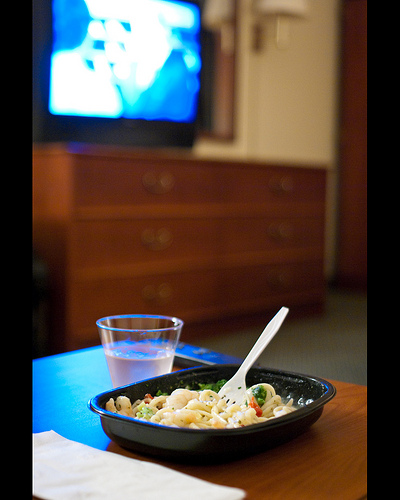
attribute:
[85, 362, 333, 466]
bowl —  black,  plastic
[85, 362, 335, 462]
container —  black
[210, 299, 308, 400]
fork — white, PLASTIC,  plastic,  white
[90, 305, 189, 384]
cup — clear, plastic,  clear ,  plastic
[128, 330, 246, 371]
remote control — for tv,  remote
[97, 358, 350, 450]
bowl —  plastic,   black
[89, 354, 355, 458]
one bowl —  one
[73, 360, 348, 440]
black bowl —  black 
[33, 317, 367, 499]
brown table —  brown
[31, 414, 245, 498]
tissue paper —   white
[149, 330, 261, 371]
remote —    one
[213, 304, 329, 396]
one fork —    one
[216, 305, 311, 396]
white fork —  white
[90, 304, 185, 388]
water glass —  one,  of water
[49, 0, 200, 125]
tv screen —  on,  of TV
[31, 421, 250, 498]
napkins —  white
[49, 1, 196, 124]
television —  on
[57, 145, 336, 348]
dresser —  brown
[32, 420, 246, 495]
napkin — white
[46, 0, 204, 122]
tv is turned — on